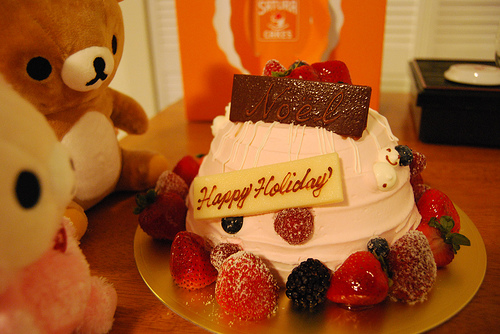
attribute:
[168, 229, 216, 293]
strawberry — red, ripe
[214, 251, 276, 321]
strawberry — red, ripe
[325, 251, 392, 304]
strawberry — red, ripe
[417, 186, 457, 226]
strawberry — red, ripe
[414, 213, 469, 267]
strawberry — red, ripe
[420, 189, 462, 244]
strawberry — ripe, red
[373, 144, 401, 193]
snowman — white, red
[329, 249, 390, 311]
strawberry — red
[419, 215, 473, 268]
strawberry — red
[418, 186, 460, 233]
strawberry — red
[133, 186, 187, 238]
strawberry — red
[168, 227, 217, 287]
strawberry — red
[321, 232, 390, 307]
strawberry — red, sugared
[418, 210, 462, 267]
strawberry — red, ripe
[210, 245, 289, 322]
srawberry — sugared, red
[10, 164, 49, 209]
toy eye — pink, white, black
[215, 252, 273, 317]
strawberry — red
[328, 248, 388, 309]
berry — sugared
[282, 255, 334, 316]
berry — sugared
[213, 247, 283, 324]
berry — sugared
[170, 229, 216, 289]
berry — sugared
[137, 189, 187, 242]
berry — sugared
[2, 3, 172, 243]
bear — brown, stuffed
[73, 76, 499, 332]
table top — wood grained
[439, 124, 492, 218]
table — brown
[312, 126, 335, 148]
drizzles — white, thin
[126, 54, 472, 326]
cake — decorated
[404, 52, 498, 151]
wooden box — small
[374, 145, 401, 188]
snowman decoration — smiley faced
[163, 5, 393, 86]
box — orange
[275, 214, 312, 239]
raspberry — sugared, red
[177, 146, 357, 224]
sign — yellow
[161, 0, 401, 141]
sign — orange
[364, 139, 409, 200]
icing — white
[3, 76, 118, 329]
animal — stuffed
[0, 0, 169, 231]
teddy bear — brown, brown and white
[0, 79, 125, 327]
teddy bear — pink